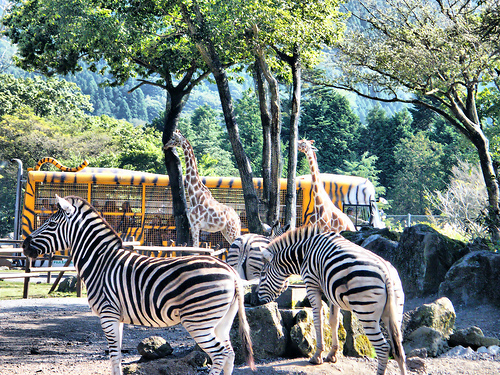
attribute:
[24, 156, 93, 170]
snake — yellow, black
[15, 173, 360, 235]
school bus — yellow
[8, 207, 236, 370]
zebra — black, white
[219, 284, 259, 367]
tail — long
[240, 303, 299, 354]
rocks — grey, large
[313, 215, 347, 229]
spots — brown, yellow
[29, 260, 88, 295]
fence — brown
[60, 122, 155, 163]
trees — big, green, large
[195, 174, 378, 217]
bus — background, yellow, long, painted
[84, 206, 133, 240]
mane — white, black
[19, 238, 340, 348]
zebras — three